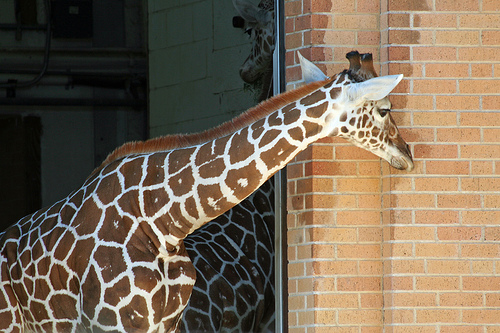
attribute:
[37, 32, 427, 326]
giraffe — white, brown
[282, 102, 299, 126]
spot — white, brown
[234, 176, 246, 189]
spots — white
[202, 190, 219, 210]
spots — white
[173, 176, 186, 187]
spots — white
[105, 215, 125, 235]
spots — white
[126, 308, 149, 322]
spots — white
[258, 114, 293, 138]
spot — white, brown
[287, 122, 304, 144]
spot — brown, white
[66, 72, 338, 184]
giraffe man — brown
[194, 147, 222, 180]
spot — brown, white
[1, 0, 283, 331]
doorway — open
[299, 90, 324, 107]
spot — brown, white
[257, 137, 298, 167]
spot — brown, white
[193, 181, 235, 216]
spot — white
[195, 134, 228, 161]
spot — brown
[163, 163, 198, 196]
spot — brown, white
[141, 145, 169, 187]
spot — brown, white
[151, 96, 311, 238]
neck — long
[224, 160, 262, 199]
spot — brown, white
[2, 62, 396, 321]
giraffes — brown, white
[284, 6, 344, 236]
stain — red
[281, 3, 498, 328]
wall — stone, brick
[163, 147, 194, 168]
spot — white, brown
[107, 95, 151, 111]
bridge — small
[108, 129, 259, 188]
neck — long